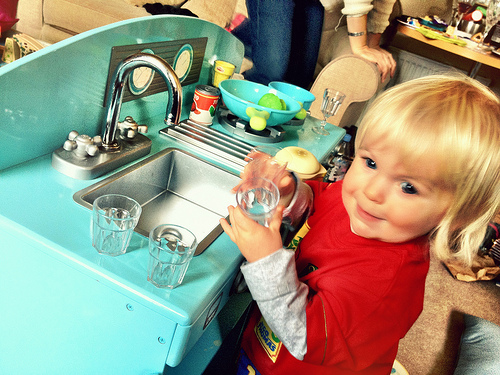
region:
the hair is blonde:
[380, 97, 442, 151]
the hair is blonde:
[407, 101, 469, 169]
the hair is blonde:
[382, 55, 490, 255]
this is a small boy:
[292, 98, 497, 373]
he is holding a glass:
[231, 177, 284, 244]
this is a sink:
[165, 168, 201, 205]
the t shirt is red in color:
[325, 255, 395, 361]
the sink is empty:
[184, 169, 209, 218]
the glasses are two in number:
[82, 197, 199, 269]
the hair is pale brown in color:
[377, 97, 478, 161]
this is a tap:
[142, 54, 177, 119]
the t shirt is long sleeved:
[255, 248, 310, 343]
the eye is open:
[395, 180, 420, 200]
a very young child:
[258, 72, 487, 367]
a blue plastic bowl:
[212, 82, 319, 129]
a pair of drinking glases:
[80, 192, 188, 289]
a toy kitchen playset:
[11, 25, 358, 373]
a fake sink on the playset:
[72, 45, 237, 245]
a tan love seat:
[3, 0, 380, 100]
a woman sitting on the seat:
[220, 2, 392, 65]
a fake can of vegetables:
[186, 80, 218, 131]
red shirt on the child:
[234, 181, 459, 373]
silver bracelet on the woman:
[331, 25, 373, 42]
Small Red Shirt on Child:
[252, 235, 427, 373]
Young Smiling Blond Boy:
[230, 71, 495, 371]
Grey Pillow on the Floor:
[448, 305, 495, 372]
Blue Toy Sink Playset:
[0, 13, 345, 371]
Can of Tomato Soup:
[186, 76, 221, 131]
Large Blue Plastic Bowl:
[217, 70, 298, 126]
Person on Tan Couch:
[218, 0, 398, 87]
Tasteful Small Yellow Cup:
[210, 55, 233, 86]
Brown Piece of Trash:
[441, 255, 496, 281]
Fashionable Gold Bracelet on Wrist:
[346, 29, 370, 38]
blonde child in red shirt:
[249, 61, 479, 367]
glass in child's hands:
[225, 161, 286, 236]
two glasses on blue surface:
[73, 186, 214, 290]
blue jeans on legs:
[244, 5, 334, 92]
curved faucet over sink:
[116, 48, 192, 193]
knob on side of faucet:
[59, 123, 105, 169]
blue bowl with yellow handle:
[214, 77, 276, 133]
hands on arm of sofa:
[344, 42, 398, 91]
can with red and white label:
[182, 80, 225, 128]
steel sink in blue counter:
[79, 144, 256, 258]